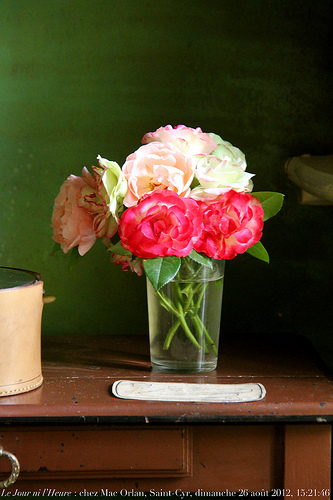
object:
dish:
[112, 379, 266, 403]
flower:
[202, 188, 264, 263]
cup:
[141, 253, 225, 374]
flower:
[117, 189, 204, 258]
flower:
[50, 166, 96, 257]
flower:
[122, 140, 195, 208]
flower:
[196, 131, 256, 190]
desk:
[2, 334, 332, 500]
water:
[147, 279, 223, 361]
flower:
[76, 154, 128, 239]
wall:
[1, 1, 332, 336]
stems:
[157, 257, 218, 356]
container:
[1, 267, 56, 399]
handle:
[0, 445, 21, 489]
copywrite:
[2, 486, 332, 499]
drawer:
[0, 424, 194, 481]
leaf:
[142, 256, 182, 293]